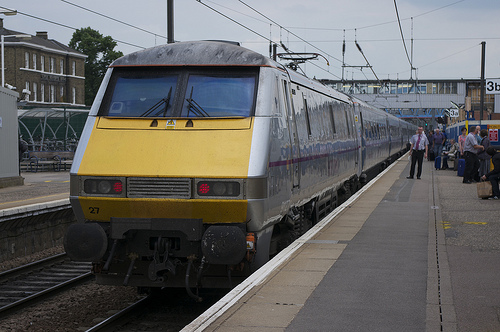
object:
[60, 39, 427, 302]
train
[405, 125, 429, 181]
man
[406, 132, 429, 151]
shirt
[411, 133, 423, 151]
red tie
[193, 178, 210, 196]
headlight